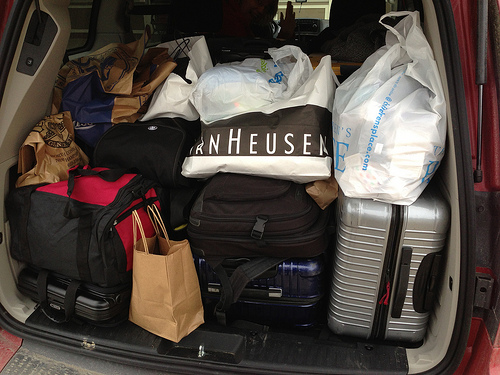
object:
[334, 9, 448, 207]
bag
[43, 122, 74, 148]
logo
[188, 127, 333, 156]
brand info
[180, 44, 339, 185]
bag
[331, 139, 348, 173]
letter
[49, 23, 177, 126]
bags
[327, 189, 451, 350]
suitcase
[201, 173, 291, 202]
small pocket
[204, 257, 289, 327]
straps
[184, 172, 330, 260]
bag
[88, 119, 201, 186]
suitcases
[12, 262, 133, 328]
suitcases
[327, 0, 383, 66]
black cows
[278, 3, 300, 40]
hand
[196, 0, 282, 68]
driver's seat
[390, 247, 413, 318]
suitcase handle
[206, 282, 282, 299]
suitcase handle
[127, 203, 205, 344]
bag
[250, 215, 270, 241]
clip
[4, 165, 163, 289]
duffel bag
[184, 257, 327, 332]
suitcase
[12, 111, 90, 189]
bag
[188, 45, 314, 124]
bag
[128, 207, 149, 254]
handle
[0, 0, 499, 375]
car